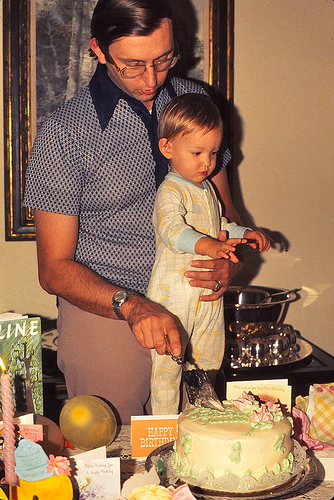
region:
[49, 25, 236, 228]
One man and baby is standing.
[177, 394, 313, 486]
Cake is on the table.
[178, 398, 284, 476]
Cake is brown and green color.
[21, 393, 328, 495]
Birthday cards on the table.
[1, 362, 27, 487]
Candle is pink color.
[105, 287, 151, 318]
Man is wearing watch in right hand.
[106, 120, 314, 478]
Man is cutting the cake.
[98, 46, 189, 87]
Man is wearing eyeglasses.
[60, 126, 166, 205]
Man is wearing black and white shirt.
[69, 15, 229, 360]
a man holding a toddler by the belly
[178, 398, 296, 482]
a birthday cake with green frosting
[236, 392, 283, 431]
candied roses on a birthday cake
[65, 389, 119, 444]
a yellow balloon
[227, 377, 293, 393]
the top of a birthday card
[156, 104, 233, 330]
toddler wearing a pajama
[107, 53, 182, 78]
man wearing glasses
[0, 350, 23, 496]
a pink spiraled candle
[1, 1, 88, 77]
a framed picture of a tree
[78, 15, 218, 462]
a man cutting a birthday cake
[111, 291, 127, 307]
this is a wrist watch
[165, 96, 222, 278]
this is a baby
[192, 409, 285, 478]
this is a cake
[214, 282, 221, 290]
this is a ring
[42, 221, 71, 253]
the lady is light skinned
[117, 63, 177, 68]
this is a spectacle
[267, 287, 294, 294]
this is a spoon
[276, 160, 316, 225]
this is a wall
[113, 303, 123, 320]
the watch is metallic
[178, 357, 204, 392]
this is a knife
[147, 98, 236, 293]
this is a child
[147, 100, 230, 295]
the child is standing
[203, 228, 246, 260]
the hand is in front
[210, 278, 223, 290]
the finger is wearing a ring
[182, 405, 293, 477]
the cake is white in color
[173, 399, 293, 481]
the cake is creamy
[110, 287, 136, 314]
this is a wrist watch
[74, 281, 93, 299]
the hand is hairy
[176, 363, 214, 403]
this is a knife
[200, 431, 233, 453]
edge of a cake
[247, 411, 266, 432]
top of a cake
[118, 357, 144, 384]
part of a cushion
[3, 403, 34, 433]
part of a candle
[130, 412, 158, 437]
part of a banner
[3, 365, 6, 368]
part of a flame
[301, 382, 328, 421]
part of a cloth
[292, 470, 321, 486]
edge of a plate